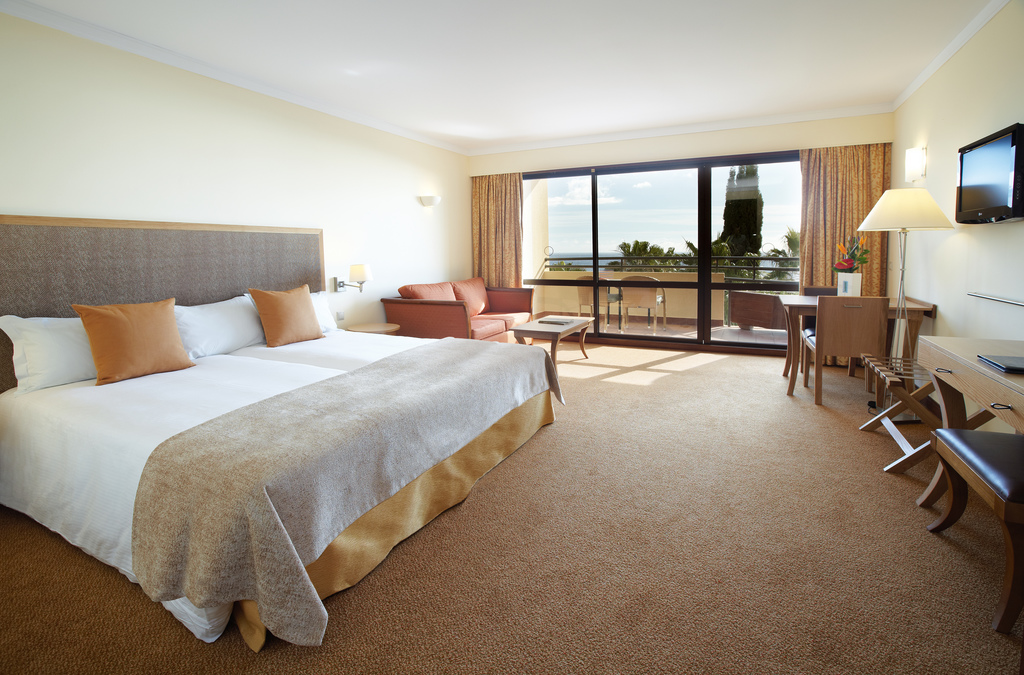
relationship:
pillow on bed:
[79, 288, 197, 396] [0, 216, 571, 647]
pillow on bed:
[246, 273, 327, 351] [0, 216, 571, 647]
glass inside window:
[520, 175, 597, 283] [497, 133, 591, 376]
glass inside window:
[595, 166, 706, 283] [577, 142, 725, 361]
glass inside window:
[710, 157, 805, 282] [694, 153, 833, 378]